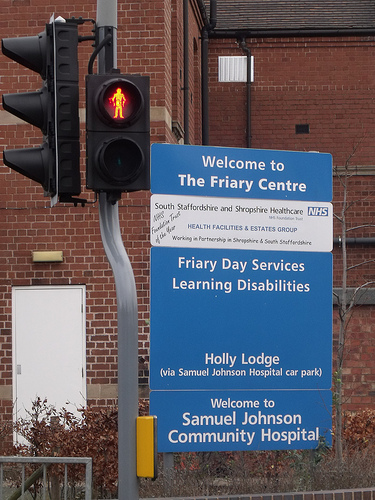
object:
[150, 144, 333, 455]
sign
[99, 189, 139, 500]
pole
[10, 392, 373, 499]
bushes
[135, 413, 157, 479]
box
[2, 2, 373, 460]
building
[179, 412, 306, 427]
samuel johnson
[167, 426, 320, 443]
community hospital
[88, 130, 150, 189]
traffic light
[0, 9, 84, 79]
traffic light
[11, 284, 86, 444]
door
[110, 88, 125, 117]
person outline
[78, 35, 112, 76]
pipes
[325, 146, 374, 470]
tree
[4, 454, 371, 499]
fencing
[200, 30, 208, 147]
rain gutter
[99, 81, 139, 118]
light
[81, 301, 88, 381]
hinges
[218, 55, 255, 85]
vent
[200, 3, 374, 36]
roof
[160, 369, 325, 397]
lettering